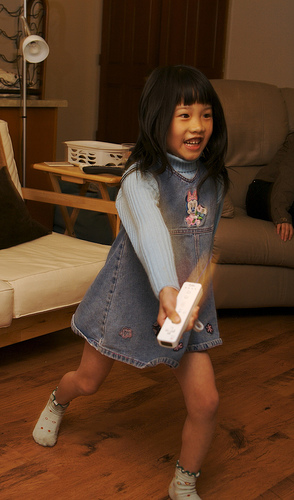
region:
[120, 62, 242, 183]
A young girl with straight black hair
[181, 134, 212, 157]
a wide open smile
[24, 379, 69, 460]
White frilly speckled socks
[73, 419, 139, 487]
wooden flooring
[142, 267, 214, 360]
a hand holding a wii remote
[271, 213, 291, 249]
The hand of a person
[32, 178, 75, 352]
part of a wooden white leather seat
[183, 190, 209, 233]
a mini mouse embroidered on a dress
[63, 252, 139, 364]
girl is wearing a jean dress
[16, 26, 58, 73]
the light and bulb of a floor lamp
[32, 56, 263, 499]
girl wearing blue denim dress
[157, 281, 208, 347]
white colored wiimote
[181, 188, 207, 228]
Minnie mouse patch on clothing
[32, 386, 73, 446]
white socks with green trim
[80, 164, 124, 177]
black plastic remote control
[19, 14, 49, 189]
white colored lamp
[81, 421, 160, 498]
section of wood floor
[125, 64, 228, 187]
girl with long straight black hair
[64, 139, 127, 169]
white plastic basket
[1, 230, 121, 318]
white fabric chair cushion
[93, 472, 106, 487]
the floor is wooden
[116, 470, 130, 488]
the floor is wooden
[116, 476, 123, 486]
the floor is wooden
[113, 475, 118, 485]
the floor is wooden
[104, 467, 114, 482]
the floor is wooden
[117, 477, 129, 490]
the floor is wooden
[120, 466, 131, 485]
the floor is wooden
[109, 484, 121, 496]
the floor is wooden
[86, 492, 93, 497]
the floor is wooden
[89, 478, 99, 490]
the floor is wooden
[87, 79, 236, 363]
The girl is wearing a blue dress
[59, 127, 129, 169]
The basket is white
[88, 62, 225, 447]
The girl is leaning forward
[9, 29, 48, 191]
A tall white lamp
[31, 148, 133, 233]
The table is made of wood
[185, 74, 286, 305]
The sofa is beige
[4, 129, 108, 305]
The chair has white cushions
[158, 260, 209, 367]
The remote control is white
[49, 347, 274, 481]
The flooring is made of wood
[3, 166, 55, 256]
The pillow is black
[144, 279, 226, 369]
girl is holding a wii remote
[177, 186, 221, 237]
minnie mouse in on her dress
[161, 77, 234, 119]
girl has bangs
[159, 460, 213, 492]
ruffles on the top of sock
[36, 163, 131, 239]
foldable table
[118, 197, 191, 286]
girls sweater is baby blue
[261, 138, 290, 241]
person's arm on the sofa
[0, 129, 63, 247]
blanket on the sofa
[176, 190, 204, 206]
minnie mouse has a pink bow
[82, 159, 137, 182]
remote on the table